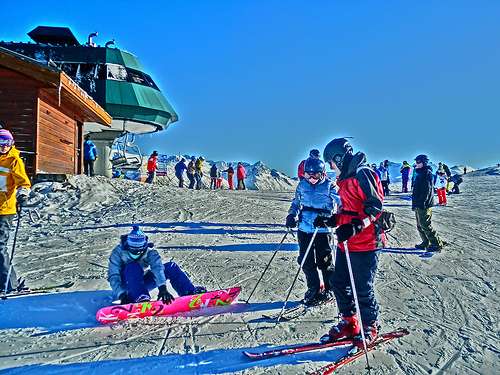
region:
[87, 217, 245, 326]
person sitting in the snow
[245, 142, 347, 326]
person on a pair of skis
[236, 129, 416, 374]
person on a pair of skis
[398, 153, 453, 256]
person standing in the snow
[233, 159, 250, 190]
person standing in the snow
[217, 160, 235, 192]
person standing in the snow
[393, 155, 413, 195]
person standing in the snow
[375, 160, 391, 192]
person standing in the snow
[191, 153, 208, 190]
person standing in the snow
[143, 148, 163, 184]
person standing in the snow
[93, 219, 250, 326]
a person strapping on a pink snowboard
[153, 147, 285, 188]
mountains in the background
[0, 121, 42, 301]
a skiier in a yellow jacket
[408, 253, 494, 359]
white snow on the hill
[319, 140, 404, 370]
a man in a red jacket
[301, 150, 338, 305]
a person in a blue jacket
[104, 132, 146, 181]
white metal ski lift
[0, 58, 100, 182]
brown wooden building on the hill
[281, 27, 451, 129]
clear blue skies over the scene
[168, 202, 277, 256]
shadows being cast on the ground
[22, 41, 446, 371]
Picture taken outside.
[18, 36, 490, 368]
Picture taken during the day.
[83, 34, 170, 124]
A large ski lift.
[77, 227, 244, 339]
A person is on the snow board.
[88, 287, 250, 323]
The snow board is pink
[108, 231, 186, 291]
The person is sitting.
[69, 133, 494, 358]
Snow covers the ground.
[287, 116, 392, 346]
Two people are standing on skis.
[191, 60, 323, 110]
The sky is void of clouds.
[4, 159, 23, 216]
A person wears a yellow jacket.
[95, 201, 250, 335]
a skateboarder on the ground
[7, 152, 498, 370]
the ground has snow on it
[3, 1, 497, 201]
a sky is blue with no clouds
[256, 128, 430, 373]
a couple of skiers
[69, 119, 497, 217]
a group of people in the background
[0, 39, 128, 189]
a wooden building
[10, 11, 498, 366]
a scene outside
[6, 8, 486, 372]
a scene during the day time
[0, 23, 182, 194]
a green building with windows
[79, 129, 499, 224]
some mountains in the background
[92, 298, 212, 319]
the snowboard is pink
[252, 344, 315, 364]
the ski's are red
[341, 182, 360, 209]
the coat is red and black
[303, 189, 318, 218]
the coat is blue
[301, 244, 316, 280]
the pants are black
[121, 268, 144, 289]
the pants are blue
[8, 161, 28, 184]
the coat is yellow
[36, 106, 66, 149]
the building is brown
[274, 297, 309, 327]
the ski's are white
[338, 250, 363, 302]
the ski pole is white